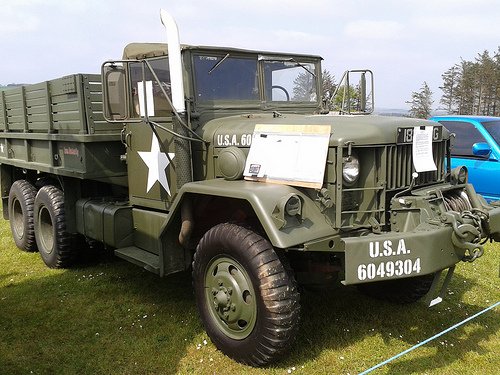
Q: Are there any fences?
A: No, there are no fences.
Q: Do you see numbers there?
A: Yes, there are numbers.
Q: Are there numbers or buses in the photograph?
A: Yes, there are numbers.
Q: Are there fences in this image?
A: No, there are no fences.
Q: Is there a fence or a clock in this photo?
A: No, there are no fences or clocks.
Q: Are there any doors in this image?
A: Yes, there is a door.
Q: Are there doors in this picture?
A: Yes, there is a door.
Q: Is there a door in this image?
A: Yes, there is a door.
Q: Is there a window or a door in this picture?
A: Yes, there is a door.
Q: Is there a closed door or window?
A: Yes, there is a closed door.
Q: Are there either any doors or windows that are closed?
A: Yes, the door is closed.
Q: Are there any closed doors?
A: Yes, there is a closed door.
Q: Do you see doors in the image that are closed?
A: Yes, there is a door that is closed.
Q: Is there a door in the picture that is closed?
A: Yes, there is a door that is closed.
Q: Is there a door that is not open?
A: Yes, there is an closed door.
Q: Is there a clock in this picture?
A: No, there are no clocks.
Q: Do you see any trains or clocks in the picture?
A: No, there are no clocks or trains.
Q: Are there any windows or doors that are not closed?
A: No, there is a door but it is closed.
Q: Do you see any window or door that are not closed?
A: No, there is a door but it is closed.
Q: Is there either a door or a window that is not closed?
A: No, there is a door but it is closed.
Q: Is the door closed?
A: Yes, the door is closed.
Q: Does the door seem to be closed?
A: Yes, the door is closed.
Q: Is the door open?
A: No, the door is closed.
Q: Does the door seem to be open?
A: No, the door is closed.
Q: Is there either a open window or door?
A: No, there is a door but it is closed.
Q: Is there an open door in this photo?
A: No, there is a door but it is closed.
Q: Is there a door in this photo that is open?
A: No, there is a door but it is closed.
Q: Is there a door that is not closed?
A: No, there is a door but it is closed.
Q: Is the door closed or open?
A: The door is closed.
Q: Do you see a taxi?
A: Yes, there is a taxi.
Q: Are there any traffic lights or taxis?
A: Yes, there is a taxi.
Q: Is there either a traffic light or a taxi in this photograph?
A: Yes, there is a taxi.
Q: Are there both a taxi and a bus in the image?
A: No, there is a taxi but no buses.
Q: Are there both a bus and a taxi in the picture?
A: No, there is a taxi but no buses.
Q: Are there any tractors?
A: No, there are no tractors.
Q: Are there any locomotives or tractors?
A: No, there are no tractors or locomotives.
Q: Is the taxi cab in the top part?
A: Yes, the taxi cab is in the top of the image.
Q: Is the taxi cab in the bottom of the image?
A: No, the taxi cab is in the top of the image.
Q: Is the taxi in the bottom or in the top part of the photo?
A: The taxi is in the top of the image.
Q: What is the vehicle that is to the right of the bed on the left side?
A: The vehicle is a taxi.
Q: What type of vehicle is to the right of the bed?
A: The vehicle is a taxi.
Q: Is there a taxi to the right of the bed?
A: Yes, there is a taxi to the right of the bed.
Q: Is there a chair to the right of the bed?
A: No, there is a taxi to the right of the bed.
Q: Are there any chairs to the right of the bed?
A: No, there is a taxi to the right of the bed.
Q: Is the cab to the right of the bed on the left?
A: Yes, the cab is to the right of the bed.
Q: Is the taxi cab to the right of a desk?
A: No, the taxi cab is to the right of the bed.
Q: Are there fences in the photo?
A: No, there are no fences.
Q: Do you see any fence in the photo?
A: No, there are no fences.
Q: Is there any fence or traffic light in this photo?
A: No, there are no fences or traffic lights.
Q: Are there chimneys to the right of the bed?
A: Yes, there is a chimney to the right of the bed.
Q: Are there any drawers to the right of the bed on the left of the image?
A: No, there is a chimney to the right of the bed.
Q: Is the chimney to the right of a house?
A: No, the chimney is to the right of a bed.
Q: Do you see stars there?
A: Yes, there is a star.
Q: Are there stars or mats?
A: Yes, there is a star.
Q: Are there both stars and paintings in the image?
A: No, there is a star but no paintings.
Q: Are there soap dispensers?
A: No, there are no soap dispensers.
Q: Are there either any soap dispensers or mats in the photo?
A: No, there are no soap dispensers or mats.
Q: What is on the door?
A: The star is on the door.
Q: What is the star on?
A: The star is on the door.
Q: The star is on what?
A: The star is on the door.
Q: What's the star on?
A: The star is on the door.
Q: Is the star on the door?
A: Yes, the star is on the door.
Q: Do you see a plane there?
A: No, there are no airplanes.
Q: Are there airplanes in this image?
A: No, there are no airplanes.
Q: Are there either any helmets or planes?
A: No, there are no planes or helmets.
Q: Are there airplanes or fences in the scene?
A: No, there are no fences or airplanes.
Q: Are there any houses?
A: No, there are no houses.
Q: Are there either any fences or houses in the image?
A: No, there are no houses or fences.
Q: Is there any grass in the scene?
A: Yes, there is grass.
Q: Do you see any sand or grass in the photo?
A: Yes, there is grass.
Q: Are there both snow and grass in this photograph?
A: No, there is grass but no snow.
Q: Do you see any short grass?
A: Yes, there is short grass.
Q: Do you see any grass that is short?
A: Yes, there is grass that is short.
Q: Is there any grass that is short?
A: Yes, there is grass that is short.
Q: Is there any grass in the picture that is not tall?
A: Yes, there is short grass.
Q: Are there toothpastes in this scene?
A: No, there are no toothpastes.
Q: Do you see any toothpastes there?
A: No, there are no toothpastes.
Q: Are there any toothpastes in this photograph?
A: No, there are no toothpastes.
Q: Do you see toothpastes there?
A: No, there are no toothpastes.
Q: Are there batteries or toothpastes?
A: No, there are no toothpastes or batteries.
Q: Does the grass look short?
A: Yes, the grass is short.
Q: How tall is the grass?
A: The grass is short.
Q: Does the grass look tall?
A: No, the grass is short.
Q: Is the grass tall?
A: No, the grass is short.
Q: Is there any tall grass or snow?
A: No, there is grass but it is short.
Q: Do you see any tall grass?
A: No, there is grass but it is short.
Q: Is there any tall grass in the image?
A: No, there is grass but it is short.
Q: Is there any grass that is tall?
A: No, there is grass but it is short.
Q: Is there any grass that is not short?
A: No, there is grass but it is short.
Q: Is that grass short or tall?
A: The grass is short.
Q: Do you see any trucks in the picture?
A: Yes, there is a truck.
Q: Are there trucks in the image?
A: Yes, there is a truck.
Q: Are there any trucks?
A: Yes, there is a truck.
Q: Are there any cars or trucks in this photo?
A: Yes, there is a truck.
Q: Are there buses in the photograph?
A: No, there are no buses.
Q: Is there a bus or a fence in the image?
A: No, there are no buses or fences.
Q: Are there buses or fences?
A: No, there are no buses or fences.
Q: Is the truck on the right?
A: Yes, the truck is on the right of the image.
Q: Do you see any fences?
A: No, there are no fences.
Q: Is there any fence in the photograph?
A: No, there are no fences.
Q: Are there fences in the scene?
A: No, there are no fences.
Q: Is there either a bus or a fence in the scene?
A: No, there are no fences or buses.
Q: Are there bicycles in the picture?
A: No, there are no bicycles.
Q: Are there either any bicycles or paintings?
A: No, there are no bicycles or paintings.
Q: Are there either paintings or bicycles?
A: No, there are no bicycles or paintings.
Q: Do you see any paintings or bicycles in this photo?
A: No, there are no bicycles or paintings.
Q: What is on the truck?
A: The chain is on the truck.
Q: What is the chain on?
A: The chain is on the truck.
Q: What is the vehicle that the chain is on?
A: The vehicle is a truck.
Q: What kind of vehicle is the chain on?
A: The chain is on the truck.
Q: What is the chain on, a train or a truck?
A: The chain is on a truck.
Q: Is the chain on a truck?
A: Yes, the chain is on a truck.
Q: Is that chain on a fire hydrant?
A: No, the chain is on a truck.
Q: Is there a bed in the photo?
A: Yes, there is a bed.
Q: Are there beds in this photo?
A: Yes, there is a bed.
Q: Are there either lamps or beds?
A: Yes, there is a bed.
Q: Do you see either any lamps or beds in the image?
A: Yes, there is a bed.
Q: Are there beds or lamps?
A: Yes, there is a bed.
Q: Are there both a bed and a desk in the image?
A: No, there is a bed but no desks.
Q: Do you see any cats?
A: No, there are no cats.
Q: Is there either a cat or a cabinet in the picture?
A: No, there are no cats or cabinets.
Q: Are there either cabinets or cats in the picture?
A: No, there are no cats or cabinets.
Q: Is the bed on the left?
A: Yes, the bed is on the left of the image.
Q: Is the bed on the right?
A: No, the bed is on the left of the image.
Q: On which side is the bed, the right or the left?
A: The bed is on the left of the image.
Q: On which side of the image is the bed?
A: The bed is on the left of the image.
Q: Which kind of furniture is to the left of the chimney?
A: The piece of furniture is a bed.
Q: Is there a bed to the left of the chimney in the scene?
A: Yes, there is a bed to the left of the chimney.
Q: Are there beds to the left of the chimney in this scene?
A: Yes, there is a bed to the left of the chimney.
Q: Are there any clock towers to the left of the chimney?
A: No, there is a bed to the left of the chimney.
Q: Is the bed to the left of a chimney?
A: Yes, the bed is to the left of a chimney.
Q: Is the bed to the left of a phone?
A: No, the bed is to the left of a chimney.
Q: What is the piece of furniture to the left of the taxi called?
A: The piece of furniture is a bed.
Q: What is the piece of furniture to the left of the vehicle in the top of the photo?
A: The piece of furniture is a bed.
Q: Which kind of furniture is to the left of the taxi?
A: The piece of furniture is a bed.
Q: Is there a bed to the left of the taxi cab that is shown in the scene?
A: Yes, there is a bed to the left of the taxi cab.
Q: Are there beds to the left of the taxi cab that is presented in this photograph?
A: Yes, there is a bed to the left of the taxi cab.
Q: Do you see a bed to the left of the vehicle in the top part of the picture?
A: Yes, there is a bed to the left of the taxi cab.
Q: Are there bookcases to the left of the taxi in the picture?
A: No, there is a bed to the left of the taxi.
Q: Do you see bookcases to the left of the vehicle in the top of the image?
A: No, there is a bed to the left of the taxi.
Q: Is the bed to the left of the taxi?
A: Yes, the bed is to the left of the taxi.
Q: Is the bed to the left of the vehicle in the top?
A: Yes, the bed is to the left of the taxi.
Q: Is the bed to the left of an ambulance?
A: No, the bed is to the left of the taxi.